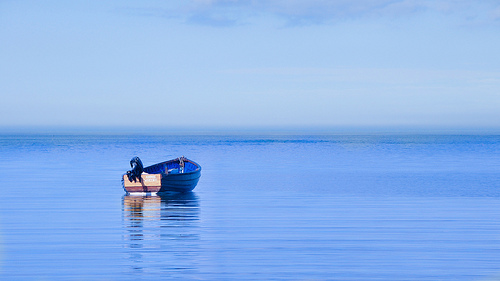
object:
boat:
[122, 156, 201, 196]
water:
[1, 139, 499, 280]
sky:
[0, 0, 499, 133]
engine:
[126, 156, 144, 182]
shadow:
[144, 161, 197, 175]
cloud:
[0, 65, 499, 125]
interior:
[143, 161, 198, 174]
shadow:
[138, 177, 151, 197]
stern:
[124, 174, 161, 192]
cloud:
[71, 0, 498, 29]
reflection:
[122, 191, 200, 273]